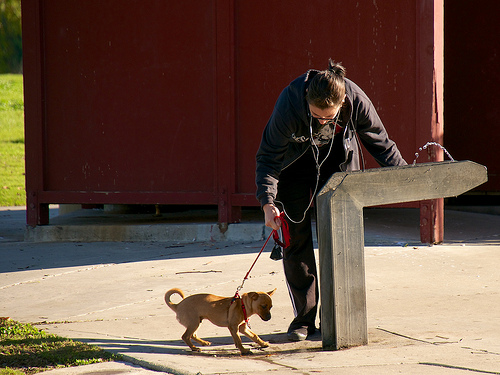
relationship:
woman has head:
[256, 56, 410, 337] [307, 57, 347, 124]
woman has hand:
[256, 56, 410, 337] [262, 197, 283, 232]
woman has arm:
[256, 56, 410, 337] [257, 93, 295, 206]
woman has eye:
[256, 56, 410, 337] [326, 112, 335, 119]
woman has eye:
[256, 56, 410, 337] [309, 111, 319, 117]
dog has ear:
[155, 286, 280, 358] [249, 292, 259, 301]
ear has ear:
[249, 292, 259, 301] [264, 287, 276, 295]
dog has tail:
[155, 286, 280, 358] [159, 284, 184, 316]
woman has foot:
[256, 56, 410, 337] [285, 314, 315, 338]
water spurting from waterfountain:
[423, 135, 461, 161] [307, 152, 492, 330]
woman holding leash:
[256, 56, 410, 337] [224, 209, 292, 329]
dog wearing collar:
[155, 286, 280, 358] [235, 298, 252, 323]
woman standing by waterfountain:
[256, 56, 410, 337] [307, 152, 492, 330]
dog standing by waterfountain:
[155, 286, 280, 358] [307, 152, 492, 330]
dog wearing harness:
[155, 286, 280, 358] [234, 269, 256, 321]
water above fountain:
[423, 135, 461, 161] [319, 160, 489, 348]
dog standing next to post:
[155, 286, 280, 358] [313, 156, 489, 354]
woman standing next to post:
[256, 56, 410, 337] [313, 156, 489, 354]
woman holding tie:
[256, 56, 410, 337] [266, 216, 287, 240]